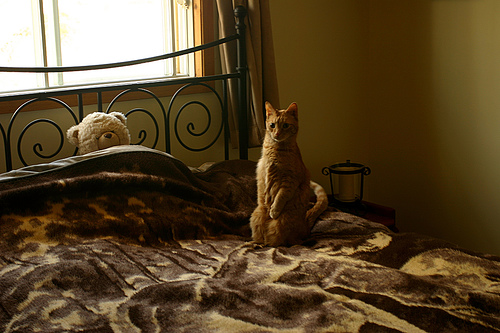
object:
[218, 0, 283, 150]
curtain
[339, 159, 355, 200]
candle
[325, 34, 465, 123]
wall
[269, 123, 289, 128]
eyes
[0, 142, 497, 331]
brown duvet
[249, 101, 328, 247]
cat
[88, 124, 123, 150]
face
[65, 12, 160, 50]
sun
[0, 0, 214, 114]
window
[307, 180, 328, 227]
tail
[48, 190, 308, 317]
blanket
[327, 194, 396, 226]
table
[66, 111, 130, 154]
teddy bear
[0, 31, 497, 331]
bed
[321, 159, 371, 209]
basin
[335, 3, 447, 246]
shadow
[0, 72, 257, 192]
bed edge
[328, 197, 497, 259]
bed edge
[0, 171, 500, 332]
covers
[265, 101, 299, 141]
head